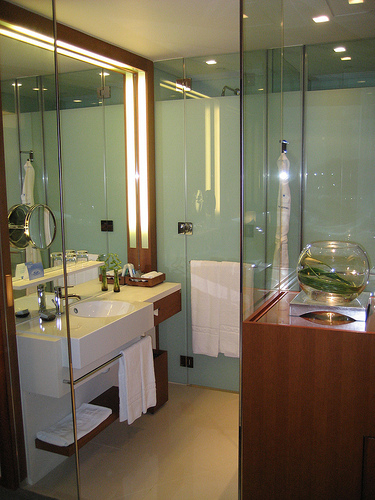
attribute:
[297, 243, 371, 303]
fishbowl — clear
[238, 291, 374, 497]
stand — wooden, brown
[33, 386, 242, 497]
floor — laquered, ceramic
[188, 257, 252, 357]
towel — white, hanging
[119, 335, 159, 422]
towel — white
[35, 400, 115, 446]
towel — white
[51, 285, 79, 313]
faucet — metal, silver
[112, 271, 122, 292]
vase — glass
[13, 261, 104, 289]
shelf — white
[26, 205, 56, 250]
mirror — circular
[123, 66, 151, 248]
light — on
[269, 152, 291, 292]
towel — white